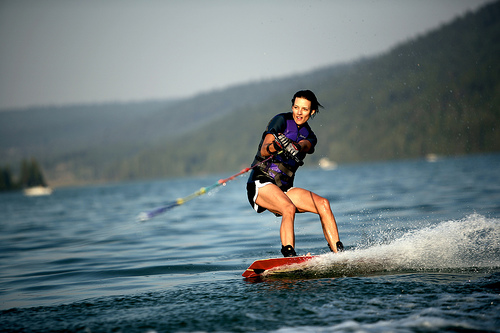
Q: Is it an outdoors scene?
A: Yes, it is outdoors.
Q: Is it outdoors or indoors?
A: It is outdoors.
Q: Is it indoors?
A: No, it is outdoors.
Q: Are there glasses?
A: No, there are no glasses.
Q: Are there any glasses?
A: No, there are no glasses.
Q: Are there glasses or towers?
A: No, there are no glasses or towers.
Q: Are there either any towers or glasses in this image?
A: No, there are no glasses or towers.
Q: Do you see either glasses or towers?
A: No, there are no glasses or towers.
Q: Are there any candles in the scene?
A: No, there are no candles.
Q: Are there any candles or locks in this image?
A: No, there are no candles or locks.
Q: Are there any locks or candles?
A: No, there are no candles or locks.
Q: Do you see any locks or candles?
A: No, there are no candles or locks.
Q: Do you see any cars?
A: No, there are no cars.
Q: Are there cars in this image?
A: No, there are no cars.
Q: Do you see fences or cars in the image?
A: No, there are no cars or fences.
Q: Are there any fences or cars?
A: No, there are no cars or fences.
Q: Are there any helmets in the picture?
A: No, there are no helmets.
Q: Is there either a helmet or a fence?
A: No, there are no helmets or fences.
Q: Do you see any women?
A: Yes, there is a woman.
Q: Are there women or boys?
A: Yes, there is a woman.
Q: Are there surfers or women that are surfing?
A: Yes, the woman is surfing.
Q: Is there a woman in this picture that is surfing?
A: Yes, there is a woman that is surfing.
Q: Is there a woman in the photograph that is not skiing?
A: Yes, there is a woman that is surfing.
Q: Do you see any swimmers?
A: No, there are no swimmers.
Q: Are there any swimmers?
A: No, there are no swimmers.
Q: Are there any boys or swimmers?
A: No, there are no swimmers or boys.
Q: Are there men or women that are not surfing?
A: No, there is a woman but she is surfing.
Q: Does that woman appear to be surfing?
A: Yes, the woman is surfing.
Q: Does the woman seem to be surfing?
A: Yes, the woman is surfing.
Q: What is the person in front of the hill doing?
A: The woman is surfing.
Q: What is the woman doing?
A: The woman is surfing.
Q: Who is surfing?
A: The woman is surfing.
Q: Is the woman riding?
A: No, the woman is surfing.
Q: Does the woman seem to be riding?
A: No, the woman is surfing.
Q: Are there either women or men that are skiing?
A: No, there is a woman but she is surfing.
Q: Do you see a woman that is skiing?
A: No, there is a woman but she is surfing.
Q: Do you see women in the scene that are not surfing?
A: No, there is a woman but she is surfing.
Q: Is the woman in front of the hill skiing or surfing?
A: The woman is surfing.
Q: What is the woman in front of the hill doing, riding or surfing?
A: The woman is surfing.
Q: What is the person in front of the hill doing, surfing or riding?
A: The woman is surfing.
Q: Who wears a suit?
A: The woman wears a suit.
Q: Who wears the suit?
A: The woman wears a suit.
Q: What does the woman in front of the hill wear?
A: The woman wears a suit.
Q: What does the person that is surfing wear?
A: The woman wears a suit.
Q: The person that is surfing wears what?
A: The woman wears a suit.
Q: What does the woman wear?
A: The woman wears a suit.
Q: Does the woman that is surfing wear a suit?
A: Yes, the woman wears a suit.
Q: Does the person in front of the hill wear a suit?
A: Yes, the woman wears a suit.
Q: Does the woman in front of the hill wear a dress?
A: No, the woman wears a suit.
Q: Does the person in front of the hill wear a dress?
A: No, the woman wears a suit.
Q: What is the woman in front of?
A: The woman is in front of the hill.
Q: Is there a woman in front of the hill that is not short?
A: Yes, there is a woman in front of the hill.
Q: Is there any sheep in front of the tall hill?
A: No, there is a woman in front of the hill.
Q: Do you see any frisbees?
A: No, there are no frisbees.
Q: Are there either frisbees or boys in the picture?
A: No, there are no frisbees or boys.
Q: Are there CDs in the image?
A: No, there are no cds.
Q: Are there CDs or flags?
A: No, there are no CDs or flags.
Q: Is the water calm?
A: Yes, the water is calm.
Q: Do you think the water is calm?
A: Yes, the water is calm.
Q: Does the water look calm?
A: Yes, the water is calm.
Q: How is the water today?
A: The water is calm.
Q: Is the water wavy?
A: No, the water is calm.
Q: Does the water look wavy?
A: No, the water is calm.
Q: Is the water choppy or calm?
A: The water is calm.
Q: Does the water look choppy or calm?
A: The water is calm.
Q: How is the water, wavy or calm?
A: The water is calm.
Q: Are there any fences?
A: No, there are no fences.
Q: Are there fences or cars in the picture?
A: No, there are no fences or cars.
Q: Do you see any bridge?
A: No, there are no bridges.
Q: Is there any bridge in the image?
A: No, there are no bridges.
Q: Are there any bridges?
A: No, there are no bridges.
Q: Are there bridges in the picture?
A: No, there are no bridges.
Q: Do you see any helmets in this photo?
A: No, there are no helmets.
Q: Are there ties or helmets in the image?
A: No, there are no helmets or ties.